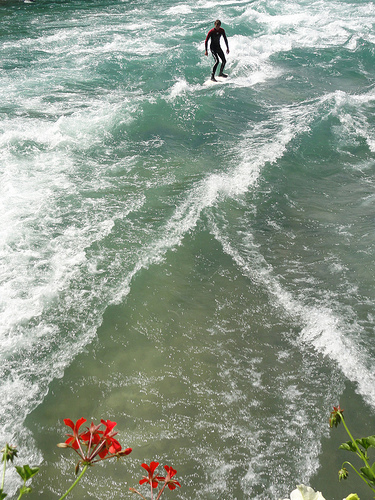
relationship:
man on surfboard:
[164, 22, 258, 116] [175, 60, 279, 117]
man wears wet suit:
[204, 19, 229, 82] [202, 26, 231, 74]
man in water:
[204, 19, 229, 82] [2, 2, 373, 498]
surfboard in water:
[147, 50, 254, 110] [18, 13, 354, 325]